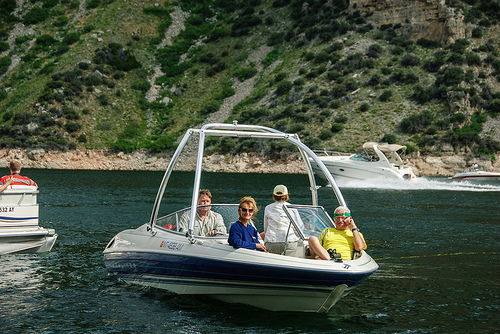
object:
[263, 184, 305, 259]
people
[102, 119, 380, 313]
boat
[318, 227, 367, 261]
shirt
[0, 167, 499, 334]
water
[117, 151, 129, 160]
rock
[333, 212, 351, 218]
foilage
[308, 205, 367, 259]
man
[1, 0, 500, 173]
hill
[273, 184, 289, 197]
cap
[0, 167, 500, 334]
river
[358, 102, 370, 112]
bush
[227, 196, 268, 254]
woman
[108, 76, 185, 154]
grass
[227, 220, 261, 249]
top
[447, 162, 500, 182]
shore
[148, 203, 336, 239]
bar